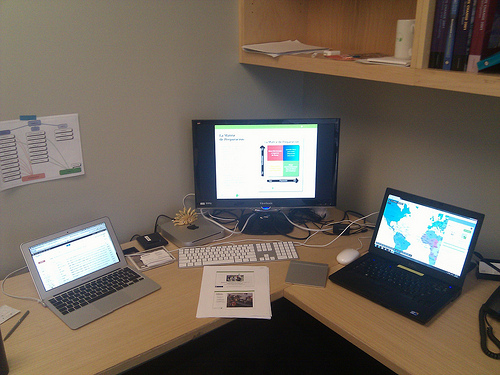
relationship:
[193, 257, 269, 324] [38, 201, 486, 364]
papers on desk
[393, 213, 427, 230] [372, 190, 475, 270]
map on screen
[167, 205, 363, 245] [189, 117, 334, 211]
wires under monitor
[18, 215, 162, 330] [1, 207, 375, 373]
laptop sitting on table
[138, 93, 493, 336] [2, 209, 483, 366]
computers on desk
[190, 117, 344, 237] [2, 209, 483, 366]
computer on desk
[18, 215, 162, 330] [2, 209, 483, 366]
laptop on desk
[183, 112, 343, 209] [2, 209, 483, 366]
monitor on desk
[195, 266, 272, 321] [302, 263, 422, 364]
papers on wooden desktop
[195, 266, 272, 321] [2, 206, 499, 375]
papers on desk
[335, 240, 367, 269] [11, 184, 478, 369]
mouse on table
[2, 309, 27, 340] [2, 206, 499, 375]
pen on desk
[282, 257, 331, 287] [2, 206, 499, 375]
pad on desk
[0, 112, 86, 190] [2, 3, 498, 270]
chart on wall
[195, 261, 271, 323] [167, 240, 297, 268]
paper in front of keyboard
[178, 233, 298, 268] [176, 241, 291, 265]
keyboard with keys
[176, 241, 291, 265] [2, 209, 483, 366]
keys on desk